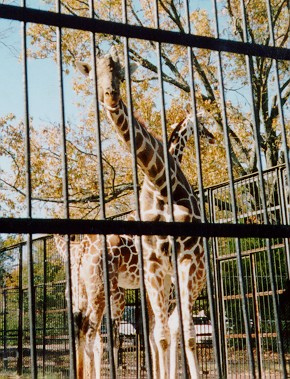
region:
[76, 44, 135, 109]
Brown and white giraffe looking at camera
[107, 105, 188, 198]
Brown and white spotted giraffe neck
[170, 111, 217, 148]
Brown and white giraffe looking to the right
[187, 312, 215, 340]
White car behind giraffe cage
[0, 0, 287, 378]
Tall black metal fence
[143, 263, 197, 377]
Tall front legs of giraffe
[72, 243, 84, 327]
Brown and white giraffe tail with black fur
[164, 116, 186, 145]
Orange mane on giraffe's neck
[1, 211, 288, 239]
Black crossbar of metal fence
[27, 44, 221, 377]
Three large giraffes in cage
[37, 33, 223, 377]
three giraffes in metal enclosure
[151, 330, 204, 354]
two giraffe knees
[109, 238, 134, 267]
brown spots on side of giraffe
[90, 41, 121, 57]
ossicones on top of giraffe head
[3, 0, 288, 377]
tall metal enclosure fence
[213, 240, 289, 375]
rusted metal door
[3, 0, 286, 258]
tall leafy tree on side of enclosure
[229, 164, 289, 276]
brown tree trunk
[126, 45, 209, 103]
brown tree branches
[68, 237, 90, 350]
brown and tan giraffe tail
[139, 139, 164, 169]
brown spotts on fur of giraffe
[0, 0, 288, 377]
tall metal fence enclosure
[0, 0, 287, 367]
trees beyond metal fence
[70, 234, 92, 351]
giraffe tail with black hair at the end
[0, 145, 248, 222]
brown tree branch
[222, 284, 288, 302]
metal rail on door of metal enclosure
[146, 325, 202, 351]
giraffe knees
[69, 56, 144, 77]
two giraffe ears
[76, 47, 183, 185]
a giraffe craning its neck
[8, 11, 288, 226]
a giraffe behind bars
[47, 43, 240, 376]
a pair of giraffe behind bars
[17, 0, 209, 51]
light orange and brown leaves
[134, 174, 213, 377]
a giraffes torso and legs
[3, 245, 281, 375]
a long black fence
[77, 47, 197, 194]
a giraffes long neck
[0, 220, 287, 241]
a long iron bar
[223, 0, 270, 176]
a long brown tree branch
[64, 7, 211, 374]
a spotted orange and brown giraffe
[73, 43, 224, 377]
giraffe in foreground facing camera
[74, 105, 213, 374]
middle giraffe facing right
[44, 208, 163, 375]
rear giraffe facing left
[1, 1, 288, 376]
black metal fence enclosure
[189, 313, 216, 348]
front of white car in distance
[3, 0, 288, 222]
yellow leaves on nearby tree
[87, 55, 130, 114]
giraffe face looking at camera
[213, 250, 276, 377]
door in fence wall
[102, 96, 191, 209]
long orange and white giraffe neck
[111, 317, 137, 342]
vehicle parked beyond fence